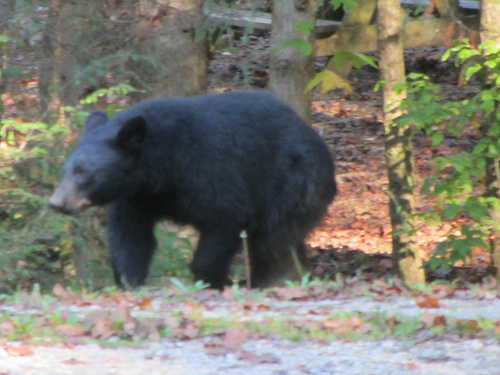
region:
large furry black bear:
[7, 77, 397, 304]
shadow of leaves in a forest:
[355, 66, 450, 326]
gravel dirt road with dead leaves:
[8, 296, 496, 373]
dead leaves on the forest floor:
[337, 98, 383, 257]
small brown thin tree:
[357, 8, 476, 300]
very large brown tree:
[22, 11, 228, 97]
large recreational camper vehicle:
[172, 15, 350, 85]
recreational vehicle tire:
[208, 58, 260, 83]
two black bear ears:
[63, 99, 180, 156]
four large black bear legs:
[78, 208, 331, 304]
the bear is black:
[8, 95, 353, 340]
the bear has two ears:
[67, 100, 143, 160]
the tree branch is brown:
[370, 25, 428, 326]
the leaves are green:
[400, 68, 488, 284]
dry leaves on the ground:
[338, 193, 381, 248]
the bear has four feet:
[112, 190, 312, 283]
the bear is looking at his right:
[35, 113, 342, 325]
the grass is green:
[156, 275, 270, 317]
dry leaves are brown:
[343, 208, 385, 248]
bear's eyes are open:
[61, 158, 111, 190]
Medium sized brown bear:
[35, 69, 345, 308]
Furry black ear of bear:
[104, 107, 159, 158]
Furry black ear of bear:
[62, 91, 116, 140]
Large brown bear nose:
[45, 178, 81, 225]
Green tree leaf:
[252, 27, 329, 64]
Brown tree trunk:
[367, 0, 438, 282]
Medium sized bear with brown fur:
[26, 63, 340, 330]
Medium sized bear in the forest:
[30, 60, 366, 315]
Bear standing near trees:
[34, 71, 369, 308]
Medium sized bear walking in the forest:
[28, 54, 361, 324]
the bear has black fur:
[46, 95, 336, 290]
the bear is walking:
[48, 91, 340, 292]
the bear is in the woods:
[48, 88, 339, 292]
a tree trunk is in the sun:
[373, 7, 430, 288]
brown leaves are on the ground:
[332, 83, 384, 369]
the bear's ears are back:
[81, 108, 149, 155]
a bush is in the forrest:
[398, 67, 498, 277]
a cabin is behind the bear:
[202, 5, 346, 45]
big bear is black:
[48, 87, 338, 292]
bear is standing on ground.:
[46, 85, 340, 296]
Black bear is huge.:
[47, 85, 338, 291]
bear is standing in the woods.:
[2, 2, 498, 299]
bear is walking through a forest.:
[1, 2, 497, 311]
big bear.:
[46, 87, 342, 290]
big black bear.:
[44, 88, 341, 293]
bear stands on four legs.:
[48, 86, 342, 290]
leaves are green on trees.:
[342, 2, 497, 284]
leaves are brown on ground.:
[3, 287, 496, 372]